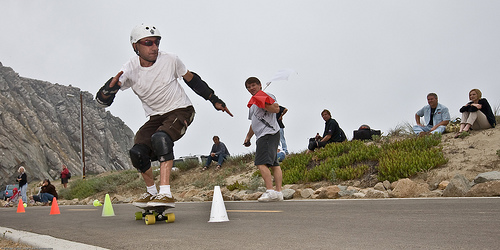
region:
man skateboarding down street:
[100, 13, 215, 237]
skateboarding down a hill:
[69, 7, 234, 248]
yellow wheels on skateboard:
[134, 210, 180, 229]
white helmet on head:
[131, 23, 156, 43]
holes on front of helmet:
[144, 23, 156, 36]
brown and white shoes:
[131, 191, 174, 203]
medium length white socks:
[129, 185, 180, 207]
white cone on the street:
[202, 184, 230, 225]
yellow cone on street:
[91, 186, 114, 225]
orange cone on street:
[48, 191, 69, 220]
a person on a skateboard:
[93, 21, 237, 205]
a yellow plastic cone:
[98, 191, 118, 216]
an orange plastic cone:
[46, 198, 62, 214]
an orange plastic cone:
[11, 197, 25, 212]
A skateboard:
[128, 198, 178, 225]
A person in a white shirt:
[240, 75, 285, 204]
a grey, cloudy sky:
[2, 1, 497, 163]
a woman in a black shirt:
[456, 83, 496, 135]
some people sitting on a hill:
[5, 85, 499, 209]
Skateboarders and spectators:
[12, 19, 490, 249]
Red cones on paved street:
[12, 193, 68, 218]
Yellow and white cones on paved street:
[96, 182, 238, 232]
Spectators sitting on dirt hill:
[415, 86, 495, 138]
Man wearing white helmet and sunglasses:
[123, 20, 167, 61]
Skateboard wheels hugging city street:
[125, 208, 180, 228]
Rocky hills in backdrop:
[0, 56, 144, 179]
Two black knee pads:
[121, 132, 181, 169]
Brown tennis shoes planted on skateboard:
[130, 191, 177, 224]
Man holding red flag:
[237, 70, 282, 115]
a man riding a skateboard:
[120, 18, 185, 233]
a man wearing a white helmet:
[112, 12, 175, 70]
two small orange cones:
[5, 194, 67, 220]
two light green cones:
[83, 179, 123, 231]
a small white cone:
[200, 171, 230, 243]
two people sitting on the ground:
[406, 83, 492, 151]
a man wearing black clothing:
[312, 96, 349, 157]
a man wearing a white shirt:
[126, 42, 190, 111]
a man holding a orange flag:
[237, 92, 297, 130]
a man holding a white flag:
[240, 52, 297, 102]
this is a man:
[97, 15, 209, 166]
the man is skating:
[106, 9, 219, 174]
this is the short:
[157, 110, 194, 130]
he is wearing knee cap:
[150, 132, 173, 157]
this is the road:
[339, 197, 443, 248]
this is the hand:
[191, 65, 228, 114]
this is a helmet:
[132, 17, 155, 34]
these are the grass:
[354, 133, 432, 170]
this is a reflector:
[205, 185, 233, 227]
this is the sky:
[322, 6, 407, 69]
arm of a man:
[176, 59, 233, 118]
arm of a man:
[102, 73, 123, 105]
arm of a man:
[260, 95, 273, 110]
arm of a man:
[245, 126, 255, 141]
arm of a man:
[317, 124, 331, 145]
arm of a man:
[415, 108, 425, 125]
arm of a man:
[430, 114, 442, 131]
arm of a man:
[211, 145, 221, 152]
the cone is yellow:
[99, 189, 118, 220]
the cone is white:
[209, 181, 229, 225]